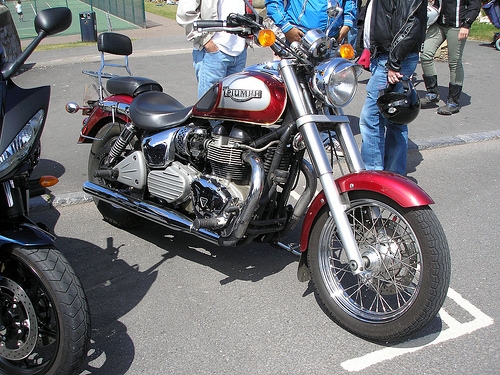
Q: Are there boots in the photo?
A: Yes, there are boots.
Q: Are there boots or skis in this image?
A: Yes, there are boots.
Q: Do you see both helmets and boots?
A: Yes, there are both boots and a helmet.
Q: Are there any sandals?
A: No, there are no sandals.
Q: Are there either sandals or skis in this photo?
A: No, there are no sandals or skis.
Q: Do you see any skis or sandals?
A: No, there are no sandals or skis.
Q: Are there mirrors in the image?
A: Yes, there is a mirror.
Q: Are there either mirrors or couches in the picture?
A: Yes, there is a mirror.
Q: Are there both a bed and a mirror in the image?
A: No, there is a mirror but no beds.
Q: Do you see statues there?
A: No, there are no statues.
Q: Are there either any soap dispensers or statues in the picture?
A: No, there are no statues or soap dispensers.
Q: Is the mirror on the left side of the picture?
A: Yes, the mirror is on the left of the image.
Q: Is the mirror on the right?
A: No, the mirror is on the left of the image.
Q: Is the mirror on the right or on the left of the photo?
A: The mirror is on the left of the image.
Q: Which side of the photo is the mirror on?
A: The mirror is on the left of the image.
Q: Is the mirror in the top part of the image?
A: Yes, the mirror is in the top of the image.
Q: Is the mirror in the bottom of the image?
A: No, the mirror is in the top of the image.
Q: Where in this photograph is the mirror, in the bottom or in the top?
A: The mirror is in the top of the image.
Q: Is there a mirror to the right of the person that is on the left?
A: Yes, there is a mirror to the right of the person.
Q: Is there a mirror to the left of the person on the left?
A: No, the mirror is to the right of the person.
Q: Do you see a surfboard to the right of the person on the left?
A: No, there is a mirror to the right of the person.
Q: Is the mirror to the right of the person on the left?
A: Yes, the mirror is to the right of the person.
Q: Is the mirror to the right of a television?
A: No, the mirror is to the right of the person.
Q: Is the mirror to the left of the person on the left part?
A: No, the mirror is to the right of the person.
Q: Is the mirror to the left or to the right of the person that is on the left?
A: The mirror is to the right of the person.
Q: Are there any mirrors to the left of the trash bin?
A: Yes, there is a mirror to the left of the trash bin.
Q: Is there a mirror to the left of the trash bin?
A: Yes, there is a mirror to the left of the trash bin.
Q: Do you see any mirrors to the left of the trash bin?
A: Yes, there is a mirror to the left of the trash bin.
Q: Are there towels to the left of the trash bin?
A: No, there is a mirror to the left of the trash bin.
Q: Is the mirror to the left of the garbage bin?
A: Yes, the mirror is to the left of the garbage bin.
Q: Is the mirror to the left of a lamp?
A: No, the mirror is to the left of the garbage bin.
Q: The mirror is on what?
A: The mirror is on the motorcycle.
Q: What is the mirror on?
A: The mirror is on the motorcycle.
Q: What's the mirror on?
A: The mirror is on the motorcycle.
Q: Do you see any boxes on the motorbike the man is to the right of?
A: No, there is a mirror on the motorcycle.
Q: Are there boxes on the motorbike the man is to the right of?
A: No, there is a mirror on the motorcycle.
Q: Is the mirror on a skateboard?
A: No, the mirror is on the motorbike.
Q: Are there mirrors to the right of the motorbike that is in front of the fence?
A: No, the mirror is to the left of the motorcycle.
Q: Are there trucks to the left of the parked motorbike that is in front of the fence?
A: No, there is a mirror to the left of the motorcycle.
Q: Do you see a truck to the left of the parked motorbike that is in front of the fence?
A: No, there is a mirror to the left of the motorcycle.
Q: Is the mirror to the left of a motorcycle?
A: Yes, the mirror is to the left of a motorcycle.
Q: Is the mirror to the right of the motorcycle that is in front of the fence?
A: No, the mirror is to the left of the motorcycle.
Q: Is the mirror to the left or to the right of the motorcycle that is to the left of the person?
A: The mirror is to the left of the motorcycle.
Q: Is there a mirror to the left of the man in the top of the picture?
A: Yes, there is a mirror to the left of the man.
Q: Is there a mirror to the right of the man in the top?
A: No, the mirror is to the left of the man.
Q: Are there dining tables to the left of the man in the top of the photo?
A: No, there is a mirror to the left of the man.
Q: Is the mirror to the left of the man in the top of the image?
A: Yes, the mirror is to the left of the man.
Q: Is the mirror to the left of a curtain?
A: No, the mirror is to the left of the man.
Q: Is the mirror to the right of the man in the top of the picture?
A: No, the mirror is to the left of the man.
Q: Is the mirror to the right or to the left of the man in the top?
A: The mirror is to the left of the man.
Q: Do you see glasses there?
A: No, there are no glasses.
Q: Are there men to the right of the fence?
A: Yes, there is a man to the right of the fence.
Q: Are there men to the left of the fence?
A: No, the man is to the right of the fence.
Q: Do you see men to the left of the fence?
A: No, the man is to the right of the fence.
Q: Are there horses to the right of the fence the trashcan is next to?
A: No, there is a man to the right of the fence.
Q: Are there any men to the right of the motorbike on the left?
A: Yes, there is a man to the right of the motorbike.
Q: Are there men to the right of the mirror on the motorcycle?
A: Yes, there is a man to the right of the mirror.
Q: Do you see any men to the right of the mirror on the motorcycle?
A: Yes, there is a man to the right of the mirror.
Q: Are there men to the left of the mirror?
A: No, the man is to the right of the mirror.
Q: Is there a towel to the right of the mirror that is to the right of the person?
A: No, there is a man to the right of the mirror.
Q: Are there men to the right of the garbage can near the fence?
A: Yes, there is a man to the right of the trashcan.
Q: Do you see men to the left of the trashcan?
A: No, the man is to the right of the trashcan.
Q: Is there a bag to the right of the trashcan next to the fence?
A: No, there is a man to the right of the garbage can.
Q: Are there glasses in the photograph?
A: No, there are no glasses.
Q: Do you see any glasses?
A: No, there are no glasses.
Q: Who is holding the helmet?
A: The man is holding the helmet.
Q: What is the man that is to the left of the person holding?
A: The man is holding the helmet.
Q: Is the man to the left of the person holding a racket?
A: No, the man is holding the helmet.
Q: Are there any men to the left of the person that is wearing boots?
A: Yes, there is a man to the left of the person.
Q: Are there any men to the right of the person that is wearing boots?
A: No, the man is to the left of the person.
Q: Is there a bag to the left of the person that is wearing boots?
A: No, there is a man to the left of the person.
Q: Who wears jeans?
A: The man wears jeans.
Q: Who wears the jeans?
A: The man wears jeans.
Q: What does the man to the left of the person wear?
A: The man wears jeans.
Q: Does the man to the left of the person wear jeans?
A: Yes, the man wears jeans.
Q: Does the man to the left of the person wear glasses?
A: No, the man wears jeans.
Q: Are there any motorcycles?
A: Yes, there is a motorcycle.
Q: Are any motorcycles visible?
A: Yes, there is a motorcycle.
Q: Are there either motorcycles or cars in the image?
A: Yes, there is a motorcycle.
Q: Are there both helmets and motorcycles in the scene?
A: Yes, there are both a motorcycle and helmets.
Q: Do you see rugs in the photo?
A: No, there are no rugs.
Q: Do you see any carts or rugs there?
A: No, there are no rugs or carts.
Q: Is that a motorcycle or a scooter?
A: That is a motorcycle.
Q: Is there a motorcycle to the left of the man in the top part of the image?
A: Yes, there is a motorcycle to the left of the man.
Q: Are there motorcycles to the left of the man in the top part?
A: Yes, there is a motorcycle to the left of the man.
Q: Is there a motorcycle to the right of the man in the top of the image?
A: No, the motorcycle is to the left of the man.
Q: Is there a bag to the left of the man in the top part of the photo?
A: No, there is a motorcycle to the left of the man.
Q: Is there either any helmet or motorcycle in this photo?
A: Yes, there is a motorcycle.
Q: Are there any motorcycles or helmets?
A: Yes, there is a motorcycle.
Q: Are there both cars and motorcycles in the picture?
A: No, there is a motorcycle but no cars.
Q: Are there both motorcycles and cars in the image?
A: No, there is a motorcycle but no cars.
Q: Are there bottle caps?
A: No, there are no bottle caps.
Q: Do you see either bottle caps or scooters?
A: No, there are no bottle caps or scooters.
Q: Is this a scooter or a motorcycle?
A: This is a motorcycle.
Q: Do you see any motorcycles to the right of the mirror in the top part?
A: Yes, there is a motorcycle to the right of the mirror.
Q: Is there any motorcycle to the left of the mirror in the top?
A: No, the motorcycle is to the right of the mirror.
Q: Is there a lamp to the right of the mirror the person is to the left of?
A: No, there is a motorcycle to the right of the mirror.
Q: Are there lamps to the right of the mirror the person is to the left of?
A: No, there is a motorcycle to the right of the mirror.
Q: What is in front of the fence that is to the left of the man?
A: The motorbike is in front of the fence.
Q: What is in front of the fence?
A: The motorbike is in front of the fence.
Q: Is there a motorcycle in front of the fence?
A: Yes, there is a motorcycle in front of the fence.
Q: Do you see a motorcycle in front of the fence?
A: Yes, there is a motorcycle in front of the fence.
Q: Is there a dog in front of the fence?
A: No, there is a motorcycle in front of the fence.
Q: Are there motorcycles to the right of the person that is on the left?
A: Yes, there is a motorcycle to the right of the person.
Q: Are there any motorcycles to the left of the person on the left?
A: No, the motorcycle is to the right of the person.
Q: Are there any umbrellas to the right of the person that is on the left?
A: No, there is a motorcycle to the right of the person.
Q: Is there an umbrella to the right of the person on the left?
A: No, there is a motorcycle to the right of the person.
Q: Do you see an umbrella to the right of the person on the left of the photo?
A: No, there is a motorcycle to the right of the person.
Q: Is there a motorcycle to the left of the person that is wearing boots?
A: Yes, there is a motorcycle to the left of the person.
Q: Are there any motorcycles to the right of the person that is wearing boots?
A: No, the motorcycle is to the left of the person.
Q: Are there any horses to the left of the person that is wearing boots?
A: No, there is a motorcycle to the left of the person.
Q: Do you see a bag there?
A: No, there are no bags.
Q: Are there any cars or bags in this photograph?
A: No, there are no bags or cars.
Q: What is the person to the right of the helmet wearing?
A: The person is wearing boots.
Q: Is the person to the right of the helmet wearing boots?
A: Yes, the person is wearing boots.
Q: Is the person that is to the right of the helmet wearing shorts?
A: No, the person is wearing boots.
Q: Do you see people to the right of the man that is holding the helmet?
A: Yes, there is a person to the right of the man.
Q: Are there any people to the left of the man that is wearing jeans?
A: No, the person is to the right of the man.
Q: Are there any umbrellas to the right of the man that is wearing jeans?
A: No, there is a person to the right of the man.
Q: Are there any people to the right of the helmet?
A: Yes, there is a person to the right of the helmet.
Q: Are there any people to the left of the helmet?
A: No, the person is to the right of the helmet.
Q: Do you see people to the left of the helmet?
A: No, the person is to the right of the helmet.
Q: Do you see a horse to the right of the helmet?
A: No, there is a person to the right of the helmet.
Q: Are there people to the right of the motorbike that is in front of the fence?
A: Yes, there is a person to the right of the motorcycle.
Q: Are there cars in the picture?
A: No, there are no cars.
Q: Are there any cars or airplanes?
A: No, there are no cars or airplanes.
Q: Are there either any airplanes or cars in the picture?
A: No, there are no cars or airplanes.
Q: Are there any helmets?
A: Yes, there is a helmet.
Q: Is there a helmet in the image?
A: Yes, there is a helmet.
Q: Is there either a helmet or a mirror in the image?
A: Yes, there is a helmet.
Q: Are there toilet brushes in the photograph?
A: No, there are no toilet brushes.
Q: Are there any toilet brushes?
A: No, there are no toilet brushes.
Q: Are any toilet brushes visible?
A: No, there are no toilet brushes.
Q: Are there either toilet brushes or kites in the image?
A: No, there are no toilet brushes or kites.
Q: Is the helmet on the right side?
A: Yes, the helmet is on the right of the image.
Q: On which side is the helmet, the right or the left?
A: The helmet is on the right of the image.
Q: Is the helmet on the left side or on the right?
A: The helmet is on the right of the image.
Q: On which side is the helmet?
A: The helmet is on the right of the image.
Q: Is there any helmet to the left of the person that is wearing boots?
A: Yes, there is a helmet to the left of the person.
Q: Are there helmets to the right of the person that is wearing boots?
A: No, the helmet is to the left of the person.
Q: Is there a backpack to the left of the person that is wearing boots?
A: No, there is a helmet to the left of the person.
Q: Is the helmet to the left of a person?
A: Yes, the helmet is to the left of a person.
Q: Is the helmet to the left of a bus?
A: No, the helmet is to the left of a person.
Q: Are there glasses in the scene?
A: No, there are no glasses.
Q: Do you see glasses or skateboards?
A: No, there are no glasses or skateboards.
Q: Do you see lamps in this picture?
A: No, there are no lamps.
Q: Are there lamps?
A: No, there are no lamps.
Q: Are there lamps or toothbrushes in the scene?
A: No, there are no lamps or toothbrushes.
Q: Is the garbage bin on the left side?
A: Yes, the garbage bin is on the left of the image.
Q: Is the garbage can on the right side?
A: No, the garbage can is on the left of the image.